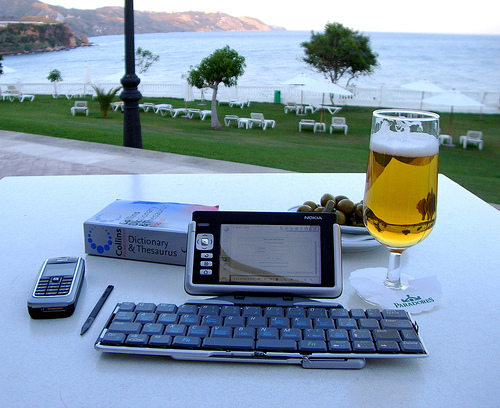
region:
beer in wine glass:
[398, 203, 414, 211]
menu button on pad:
[198, 235, 208, 241]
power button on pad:
[201, 250, 213, 259]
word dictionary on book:
[123, 231, 180, 246]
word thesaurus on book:
[134, 243, 183, 258]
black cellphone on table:
[27, 242, 84, 322]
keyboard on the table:
[90, 268, 420, 367]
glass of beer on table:
[334, 100, 451, 315]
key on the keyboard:
[276, 326, 301, 340]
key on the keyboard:
[257, 325, 278, 339]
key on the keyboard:
[305, 328, 325, 343]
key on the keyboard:
[330, 327, 346, 339]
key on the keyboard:
[349, 327, 369, 341]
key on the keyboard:
[377, 339, 395, 355]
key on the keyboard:
[150, 330, 167, 347]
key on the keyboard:
[255, 337, 300, 349]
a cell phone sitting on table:
[35, 225, 85, 330]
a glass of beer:
[369, 98, 467, 306]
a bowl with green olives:
[306, 184, 378, 245]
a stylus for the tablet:
[81, 284, 128, 341]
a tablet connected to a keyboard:
[182, 187, 372, 375]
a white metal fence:
[35, 83, 497, 116]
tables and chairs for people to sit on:
[222, 111, 349, 138]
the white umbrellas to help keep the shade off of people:
[287, 63, 353, 134]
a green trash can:
[265, 77, 285, 117]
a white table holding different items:
[27, 164, 495, 406]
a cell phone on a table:
[23, 248, 93, 323]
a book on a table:
[80, 182, 184, 259]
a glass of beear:
[353, 95, 438, 299]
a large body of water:
[375, 23, 476, 90]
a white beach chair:
[245, 111, 280, 138]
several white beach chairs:
[218, 111, 350, 135]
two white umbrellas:
[274, 70, 363, 105]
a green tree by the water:
[303, 6, 377, 135]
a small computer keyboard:
[98, 304, 428, 358]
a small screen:
[192, 213, 340, 286]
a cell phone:
[26, 242, 85, 318]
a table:
[57, 374, 96, 400]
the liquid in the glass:
[371, 165, 429, 247]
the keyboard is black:
[123, 300, 414, 360]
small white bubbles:
[401, 143, 424, 158]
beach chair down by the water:
[244, 106, 275, 133]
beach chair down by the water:
[330, 112, 355, 138]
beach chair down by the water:
[295, 115, 313, 136]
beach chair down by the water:
[456, 125, 483, 155]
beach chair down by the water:
[160, 98, 191, 116]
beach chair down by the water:
[138, 98, 169, 118]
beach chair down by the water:
[68, 98, 89, 115]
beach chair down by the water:
[276, 95, 301, 118]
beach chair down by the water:
[300, 100, 313, 115]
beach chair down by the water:
[229, 115, 249, 128]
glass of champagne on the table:
[362, 107, 439, 311]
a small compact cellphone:
[28, 254, 83, 317]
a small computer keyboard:
[92, 297, 430, 369]